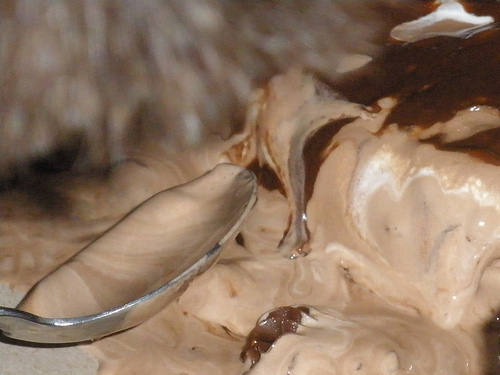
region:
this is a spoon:
[21, 160, 253, 344]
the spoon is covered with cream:
[30, 159, 267, 334]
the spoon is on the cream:
[4, 300, 188, 351]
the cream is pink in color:
[361, 167, 458, 351]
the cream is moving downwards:
[282, 113, 387, 261]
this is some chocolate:
[401, 37, 472, 107]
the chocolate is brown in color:
[422, 70, 479, 98]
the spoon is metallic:
[5, 320, 77, 343]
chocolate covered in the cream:
[252, 310, 339, 360]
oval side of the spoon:
[61, 177, 258, 324]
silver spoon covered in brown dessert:
[5, 233, 242, 363]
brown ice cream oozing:
[51, 100, 480, 349]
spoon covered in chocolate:
[30, 129, 294, 365]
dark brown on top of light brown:
[341, 20, 490, 208]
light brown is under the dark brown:
[206, 64, 485, 296]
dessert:
[30, 44, 471, 325]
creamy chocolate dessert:
[157, 38, 462, 355]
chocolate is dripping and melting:
[43, 60, 475, 370]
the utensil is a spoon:
[17, 32, 315, 373]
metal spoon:
[1, 235, 263, 348]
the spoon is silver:
[26, 180, 262, 325]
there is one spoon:
[40, 191, 240, 311]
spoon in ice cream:
[35, 165, 260, 330]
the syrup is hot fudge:
[357, 45, 487, 157]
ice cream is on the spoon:
[37, 166, 260, 326]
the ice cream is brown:
[256, 171, 477, 350]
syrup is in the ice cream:
[377, 55, 497, 142]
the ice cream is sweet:
[240, 235, 475, 365]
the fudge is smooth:
[366, 53, 496, 133]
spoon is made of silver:
[38, 130, 251, 351]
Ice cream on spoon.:
[5, 140, 362, 343]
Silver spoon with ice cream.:
[20, 175, 321, 370]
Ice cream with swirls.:
[247, 64, 477, 213]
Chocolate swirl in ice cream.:
[300, 35, 460, 176]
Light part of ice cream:
[321, 153, 480, 275]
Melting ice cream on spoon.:
[65, 152, 230, 374]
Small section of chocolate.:
[230, 294, 305, 371]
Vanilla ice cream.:
[348, 197, 460, 316]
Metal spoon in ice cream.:
[15, 306, 145, 355]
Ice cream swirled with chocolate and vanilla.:
[216, 91, 361, 243]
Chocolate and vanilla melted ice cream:
[278, 141, 402, 286]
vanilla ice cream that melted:
[355, 147, 395, 217]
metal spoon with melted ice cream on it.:
[1, 164, 260, 344]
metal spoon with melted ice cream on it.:
[3, 165, 271, 345]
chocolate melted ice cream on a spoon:
[107, 223, 177, 283]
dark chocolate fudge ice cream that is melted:
[306, 121, 331, 173]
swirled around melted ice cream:
[352, 153, 448, 267]